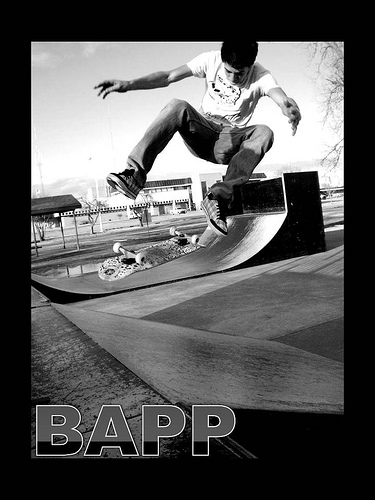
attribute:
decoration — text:
[35, 404, 236, 455]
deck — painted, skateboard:
[99, 235, 201, 282]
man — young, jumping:
[93, 41, 302, 238]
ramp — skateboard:
[206, 210, 287, 276]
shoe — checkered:
[200, 194, 228, 237]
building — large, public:
[106, 176, 195, 223]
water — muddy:
[41, 263, 98, 280]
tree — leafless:
[302, 42, 342, 180]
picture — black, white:
[30, 40, 344, 458]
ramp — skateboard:
[178, 215, 288, 279]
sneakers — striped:
[107, 168, 229, 236]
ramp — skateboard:
[31, 211, 286, 303]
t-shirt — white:
[185, 49, 281, 127]